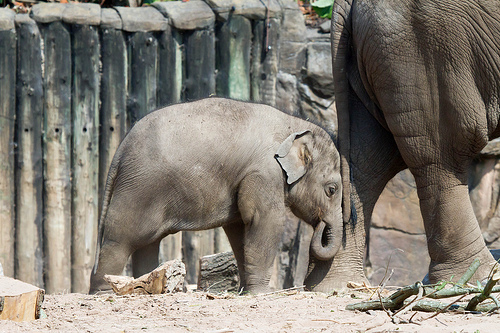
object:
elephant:
[88, 96, 346, 294]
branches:
[342, 261, 497, 313]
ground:
[7, 293, 495, 333]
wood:
[0, 274, 48, 322]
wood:
[102, 257, 189, 296]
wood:
[197, 249, 242, 293]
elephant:
[295, 0, 500, 301]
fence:
[2, 4, 262, 293]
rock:
[62, 4, 105, 25]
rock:
[117, 6, 165, 34]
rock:
[160, 0, 215, 27]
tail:
[89, 128, 133, 274]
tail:
[329, 4, 357, 248]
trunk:
[308, 215, 346, 262]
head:
[285, 115, 349, 259]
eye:
[324, 183, 339, 196]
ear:
[274, 128, 319, 188]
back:
[131, 95, 322, 127]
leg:
[244, 175, 281, 296]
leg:
[222, 225, 247, 294]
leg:
[86, 162, 169, 292]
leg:
[131, 238, 165, 275]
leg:
[376, 66, 499, 294]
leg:
[302, 89, 409, 290]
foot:
[431, 259, 500, 291]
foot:
[306, 270, 374, 296]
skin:
[113, 107, 289, 226]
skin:
[343, 6, 499, 132]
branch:
[422, 259, 500, 296]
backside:
[109, 117, 165, 174]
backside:
[348, 3, 452, 112]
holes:
[22, 126, 31, 136]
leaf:
[311, 2, 334, 19]